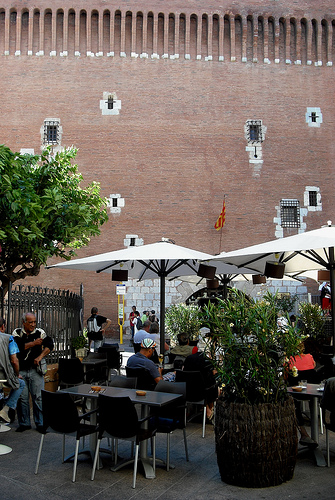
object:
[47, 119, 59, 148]
window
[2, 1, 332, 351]
building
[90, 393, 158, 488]
chair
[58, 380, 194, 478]
table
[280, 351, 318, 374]
object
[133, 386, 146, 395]
bowl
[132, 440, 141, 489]
leg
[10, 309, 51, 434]
man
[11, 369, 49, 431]
blue jeans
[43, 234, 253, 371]
umbrella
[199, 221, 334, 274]
umbrella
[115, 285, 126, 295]
sign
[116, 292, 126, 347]
pole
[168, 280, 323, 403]
plant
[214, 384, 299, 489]
barrel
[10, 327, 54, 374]
shirt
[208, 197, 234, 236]
flas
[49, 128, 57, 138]
bars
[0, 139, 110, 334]
tree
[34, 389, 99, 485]
chairs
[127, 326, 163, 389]
man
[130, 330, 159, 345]
cap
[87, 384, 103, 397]
ashtray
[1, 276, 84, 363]
fence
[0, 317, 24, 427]
man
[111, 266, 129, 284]
lights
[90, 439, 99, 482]
legs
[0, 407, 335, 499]
sidewalk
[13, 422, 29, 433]
shoes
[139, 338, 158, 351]
cap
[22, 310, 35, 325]
hair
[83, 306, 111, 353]
person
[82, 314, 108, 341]
shirt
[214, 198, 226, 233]
flag